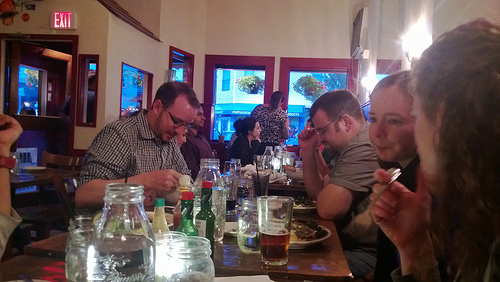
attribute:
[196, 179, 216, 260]
bottle — hot, green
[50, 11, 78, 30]
exit sign — lit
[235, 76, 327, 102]
flowering plants — hanging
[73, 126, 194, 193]
shirt sleeves — rolled up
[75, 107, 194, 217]
shirt — squared